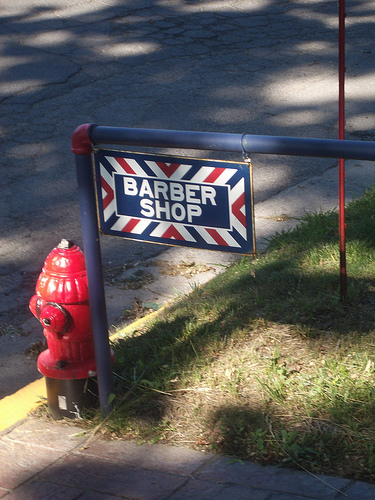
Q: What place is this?
A: It is a road.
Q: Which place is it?
A: It is a road.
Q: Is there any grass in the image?
A: Yes, there is grass.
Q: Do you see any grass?
A: Yes, there is grass.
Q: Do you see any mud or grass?
A: Yes, there is grass.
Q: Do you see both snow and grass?
A: No, there is grass but no snow.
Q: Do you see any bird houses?
A: No, there are no bird houses.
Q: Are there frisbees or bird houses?
A: No, there are no bird houses or frisbees.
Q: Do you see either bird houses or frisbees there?
A: No, there are no bird houses or frisbees.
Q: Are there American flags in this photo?
A: No, there are no American flags.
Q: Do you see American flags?
A: No, there are no American flags.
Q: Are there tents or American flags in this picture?
A: No, there are no American flags or tents.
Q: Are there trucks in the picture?
A: No, there are no trucks.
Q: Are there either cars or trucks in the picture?
A: No, there are no trucks or cars.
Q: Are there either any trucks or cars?
A: No, there are no trucks or cars.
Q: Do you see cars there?
A: No, there are no cars.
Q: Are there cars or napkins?
A: No, there are no cars or napkins.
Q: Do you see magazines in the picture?
A: No, there are no magazines.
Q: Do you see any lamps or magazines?
A: No, there are no magazines or lamps.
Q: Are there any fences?
A: No, there are no fences.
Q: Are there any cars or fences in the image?
A: No, there are no fences or cars.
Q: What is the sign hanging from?
A: The sign is hanging from the pole.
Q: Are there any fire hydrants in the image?
A: Yes, there is a fire hydrant.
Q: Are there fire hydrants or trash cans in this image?
A: Yes, there is a fire hydrant.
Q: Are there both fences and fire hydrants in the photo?
A: No, there is a fire hydrant but no fences.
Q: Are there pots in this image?
A: No, there are no pots.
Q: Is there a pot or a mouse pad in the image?
A: No, there are no pots or mouse pads.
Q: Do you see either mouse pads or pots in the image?
A: No, there are no pots or mouse pads.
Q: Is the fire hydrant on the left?
A: Yes, the fire hydrant is on the left of the image.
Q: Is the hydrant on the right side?
A: No, the hydrant is on the left of the image.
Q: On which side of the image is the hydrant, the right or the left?
A: The hydrant is on the left of the image.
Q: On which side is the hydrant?
A: The hydrant is on the left of the image.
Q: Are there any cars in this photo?
A: No, there are no cars.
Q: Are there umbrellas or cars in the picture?
A: No, there are no cars or umbrellas.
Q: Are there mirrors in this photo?
A: No, there are no mirrors.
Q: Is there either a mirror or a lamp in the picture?
A: No, there are no mirrors or lamps.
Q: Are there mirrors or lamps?
A: No, there are no mirrors or lamps.